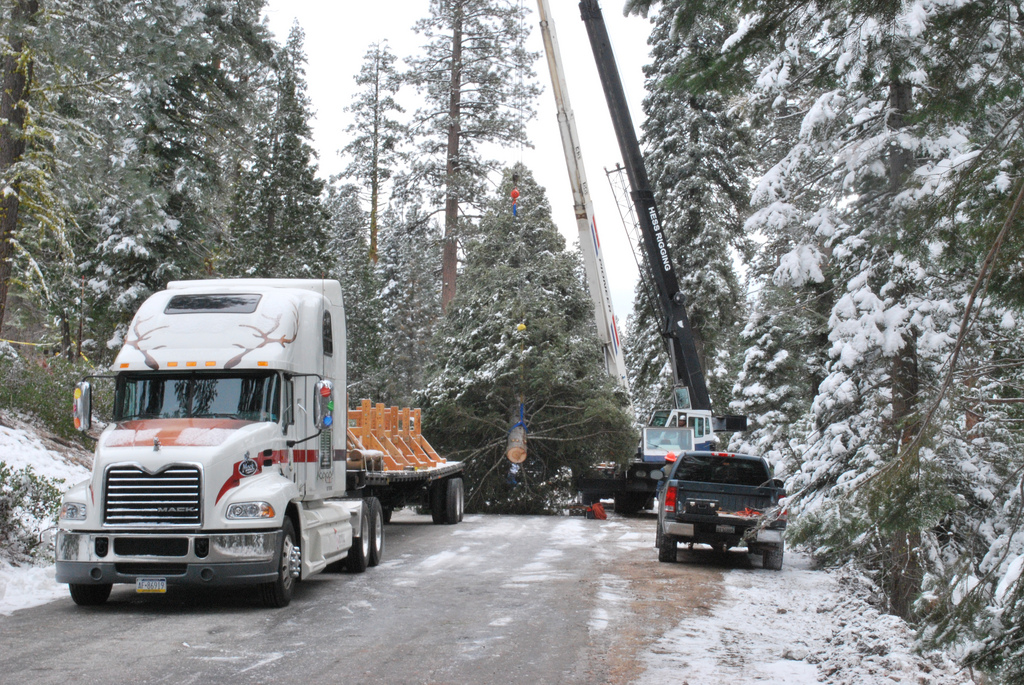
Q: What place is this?
A: It is a road.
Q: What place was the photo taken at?
A: It was taken at the road.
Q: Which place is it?
A: It is a road.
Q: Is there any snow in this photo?
A: Yes, there is snow.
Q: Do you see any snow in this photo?
A: Yes, there is snow.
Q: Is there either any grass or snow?
A: Yes, there is snow.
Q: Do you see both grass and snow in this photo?
A: No, there is snow but no grass.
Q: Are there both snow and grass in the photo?
A: No, there is snow but no grass.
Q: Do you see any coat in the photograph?
A: No, there are no coats.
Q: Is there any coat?
A: No, there are no coats.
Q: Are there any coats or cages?
A: No, there are no coats or cages.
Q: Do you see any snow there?
A: Yes, there is snow.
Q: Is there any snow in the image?
A: Yes, there is snow.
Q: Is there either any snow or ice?
A: Yes, there is snow.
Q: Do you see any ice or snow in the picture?
A: Yes, there is snow.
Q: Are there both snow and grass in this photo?
A: No, there is snow but no grass.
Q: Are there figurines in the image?
A: No, there are no figurines.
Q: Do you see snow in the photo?
A: Yes, there is snow.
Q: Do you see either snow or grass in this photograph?
A: Yes, there is snow.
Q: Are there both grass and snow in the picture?
A: No, there is snow but no grass.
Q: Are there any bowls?
A: No, there are no bowls.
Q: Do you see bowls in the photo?
A: No, there are no bowls.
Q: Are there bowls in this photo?
A: No, there are no bowls.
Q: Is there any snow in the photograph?
A: Yes, there is snow.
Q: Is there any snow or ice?
A: Yes, there is snow.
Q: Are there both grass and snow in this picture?
A: No, there is snow but no grass.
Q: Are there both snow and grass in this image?
A: No, there is snow but no grass.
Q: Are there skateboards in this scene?
A: No, there are no skateboards.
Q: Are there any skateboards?
A: No, there are no skateboards.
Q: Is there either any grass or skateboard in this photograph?
A: No, there are no skateboards or grass.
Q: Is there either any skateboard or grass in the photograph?
A: No, there are no skateboards or grass.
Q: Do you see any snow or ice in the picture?
A: Yes, there is snow.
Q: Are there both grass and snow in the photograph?
A: No, there is snow but no grass.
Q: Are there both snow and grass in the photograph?
A: No, there is snow but no grass.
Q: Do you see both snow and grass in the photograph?
A: No, there is snow but no grass.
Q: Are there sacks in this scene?
A: No, there are no sacks.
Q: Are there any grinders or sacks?
A: No, there are no sacks or grinders.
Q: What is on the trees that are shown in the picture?
A: The snow is on the trees.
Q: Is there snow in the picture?
A: Yes, there is snow.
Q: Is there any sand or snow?
A: Yes, there is snow.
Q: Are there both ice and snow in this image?
A: No, there is snow but no ice.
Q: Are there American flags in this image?
A: No, there are no American flags.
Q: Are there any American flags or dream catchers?
A: No, there are no American flags or dream catchers.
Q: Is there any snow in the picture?
A: Yes, there is snow.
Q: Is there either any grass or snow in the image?
A: Yes, there is snow.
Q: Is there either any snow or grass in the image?
A: Yes, there is snow.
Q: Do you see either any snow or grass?
A: Yes, there is snow.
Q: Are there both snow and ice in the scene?
A: No, there is snow but no ice.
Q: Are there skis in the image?
A: No, there are no skis.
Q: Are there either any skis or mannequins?
A: No, there are no skis or mannequins.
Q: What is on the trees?
A: The snow is on the trees.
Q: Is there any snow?
A: Yes, there is snow.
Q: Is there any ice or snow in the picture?
A: Yes, there is snow.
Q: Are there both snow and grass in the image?
A: No, there is snow but no grass.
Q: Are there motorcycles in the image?
A: No, there are no motorcycles.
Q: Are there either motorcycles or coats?
A: No, there are no motorcycles or coats.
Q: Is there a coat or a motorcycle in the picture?
A: No, there are no motorcycles or coats.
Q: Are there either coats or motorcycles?
A: No, there are no motorcycles or coats.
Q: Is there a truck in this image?
A: Yes, there is a truck.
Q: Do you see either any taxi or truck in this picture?
A: Yes, there is a truck.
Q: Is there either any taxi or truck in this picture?
A: Yes, there is a truck.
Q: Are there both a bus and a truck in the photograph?
A: No, there is a truck but no buses.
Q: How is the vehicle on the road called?
A: The vehicle is a truck.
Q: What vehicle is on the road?
A: The vehicle is a truck.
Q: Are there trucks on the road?
A: Yes, there is a truck on the road.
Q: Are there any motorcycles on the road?
A: No, there is a truck on the road.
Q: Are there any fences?
A: No, there are no fences.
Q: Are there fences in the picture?
A: No, there are no fences.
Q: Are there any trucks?
A: Yes, there is a truck.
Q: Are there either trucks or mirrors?
A: Yes, there is a truck.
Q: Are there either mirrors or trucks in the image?
A: Yes, there is a truck.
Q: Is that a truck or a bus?
A: That is a truck.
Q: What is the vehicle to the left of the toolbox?
A: The vehicle is a truck.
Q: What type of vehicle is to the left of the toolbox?
A: The vehicle is a truck.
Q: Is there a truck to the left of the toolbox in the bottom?
A: Yes, there is a truck to the left of the toolbox.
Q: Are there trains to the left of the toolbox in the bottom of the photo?
A: No, there is a truck to the left of the toolbox.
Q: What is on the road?
A: The truck is on the road.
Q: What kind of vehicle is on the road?
A: The vehicle is a truck.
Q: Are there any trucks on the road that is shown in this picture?
A: Yes, there is a truck on the road.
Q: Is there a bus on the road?
A: No, there is a truck on the road.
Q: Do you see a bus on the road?
A: No, there is a truck on the road.